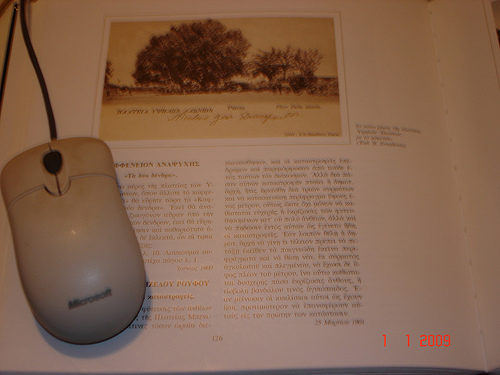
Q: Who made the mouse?
A: Microsoft.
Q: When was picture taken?
A: 1/1/2009.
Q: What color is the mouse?
A: Gray.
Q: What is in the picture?
A: Trees.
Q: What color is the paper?
A: White.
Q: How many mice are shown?
A: One.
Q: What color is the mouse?
A: White.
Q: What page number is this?
A: 126.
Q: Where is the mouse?
A: On the book page.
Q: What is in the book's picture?
A: A tree.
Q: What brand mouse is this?
A: Microsoft.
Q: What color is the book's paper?
A: White.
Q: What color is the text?
A: Black.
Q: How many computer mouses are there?
A: One.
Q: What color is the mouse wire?
A: Black.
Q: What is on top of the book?
A: Computer mouse.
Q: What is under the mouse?
A: Open book.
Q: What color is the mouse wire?
A: Black.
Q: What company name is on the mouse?
A: Microsoft.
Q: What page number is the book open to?
A: 126.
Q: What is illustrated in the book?
A: Trees.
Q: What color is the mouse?
A: Grey.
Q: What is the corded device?
A: A mouse.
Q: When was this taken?
A: January 1, 2009.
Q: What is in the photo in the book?
A: Trees.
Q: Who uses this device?
A: A computer operator.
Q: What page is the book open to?
A: 126.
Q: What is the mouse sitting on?
A: An open book.